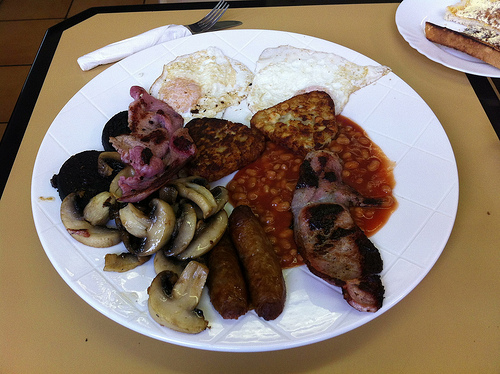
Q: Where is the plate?
A: On the table.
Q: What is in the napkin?
A: Knife and fork.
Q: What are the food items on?
A: Plate.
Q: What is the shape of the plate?
A: Round.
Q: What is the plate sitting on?
A: Table.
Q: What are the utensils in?
A: Napkin.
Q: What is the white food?
A: Eggs.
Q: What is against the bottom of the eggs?
A: Hash browns.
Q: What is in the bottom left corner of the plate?
A: Mushrooms.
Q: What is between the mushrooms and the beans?
A: Sausage.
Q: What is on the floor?
A: Tile.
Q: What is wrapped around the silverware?
A: A napkin.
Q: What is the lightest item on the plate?
A: Eggs.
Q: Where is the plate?
A: On a table.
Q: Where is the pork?
A: On top of the beans.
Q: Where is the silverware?
A: At the top of the plate.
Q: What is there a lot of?
A: Mushrooms.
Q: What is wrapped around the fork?
A: A napkin.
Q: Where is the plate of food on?
A: A table.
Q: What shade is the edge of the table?
A: Black.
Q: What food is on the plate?
A: Toast.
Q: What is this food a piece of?
A: Meat.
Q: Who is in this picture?
A: No one.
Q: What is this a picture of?
A: Meal.